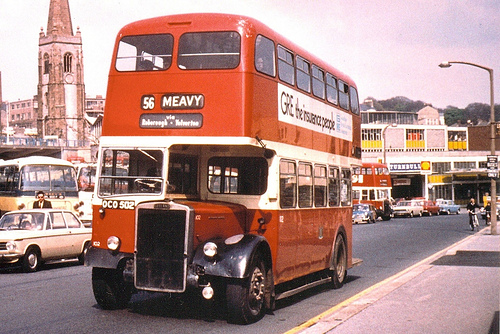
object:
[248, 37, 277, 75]
glass window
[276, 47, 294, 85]
glass window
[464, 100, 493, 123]
trees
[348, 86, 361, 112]
windows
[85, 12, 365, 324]
bus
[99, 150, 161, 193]
window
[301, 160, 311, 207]
window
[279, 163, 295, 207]
window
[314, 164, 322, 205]
window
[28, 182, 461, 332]
street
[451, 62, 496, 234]
lamp post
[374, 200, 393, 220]
cars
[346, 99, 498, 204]
buildings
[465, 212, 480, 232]
bicycle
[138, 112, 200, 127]
sign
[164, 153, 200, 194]
windows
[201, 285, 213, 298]
lights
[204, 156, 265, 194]
window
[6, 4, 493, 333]
city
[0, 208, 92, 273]
car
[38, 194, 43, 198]
sunglasses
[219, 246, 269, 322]
wheel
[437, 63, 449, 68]
light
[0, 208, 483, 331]
road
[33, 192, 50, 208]
man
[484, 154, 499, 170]
sign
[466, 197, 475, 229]
man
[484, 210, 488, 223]
bicycle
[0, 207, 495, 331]
street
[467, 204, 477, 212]
sweater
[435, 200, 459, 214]
car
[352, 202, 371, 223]
car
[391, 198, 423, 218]
cars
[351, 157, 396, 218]
truck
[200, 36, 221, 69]
woman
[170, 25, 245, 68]
window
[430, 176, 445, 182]
station sign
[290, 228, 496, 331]
sidewalk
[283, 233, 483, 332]
curb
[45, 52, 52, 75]
belfry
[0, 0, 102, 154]
church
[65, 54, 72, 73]
spires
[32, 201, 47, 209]
suit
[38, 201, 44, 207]
tie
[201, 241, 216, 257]
headlight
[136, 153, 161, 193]
bus driver